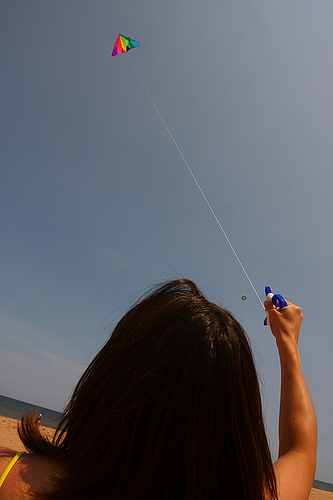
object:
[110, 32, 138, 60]
kite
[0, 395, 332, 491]
water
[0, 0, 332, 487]
blue sky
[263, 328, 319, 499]
arm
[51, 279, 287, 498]
head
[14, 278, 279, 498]
hair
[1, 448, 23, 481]
bathing suit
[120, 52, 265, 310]
string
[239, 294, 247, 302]
kite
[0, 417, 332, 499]
sand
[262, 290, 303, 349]
hand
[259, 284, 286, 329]
handle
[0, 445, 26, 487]
strap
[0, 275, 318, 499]
person